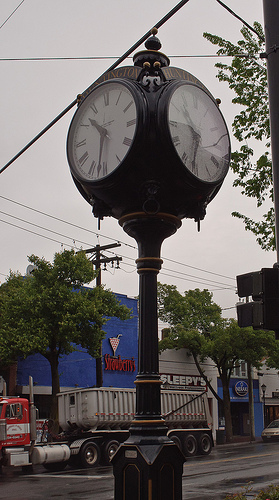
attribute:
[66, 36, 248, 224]
clock — in the picture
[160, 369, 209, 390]
sign — sleepy's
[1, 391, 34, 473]
truck cab — red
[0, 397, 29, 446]
cab — red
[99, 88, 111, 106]
12 — in the picture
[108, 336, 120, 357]
glass — margarita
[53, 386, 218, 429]
trailer — grey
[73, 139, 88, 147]
numeral — in the picture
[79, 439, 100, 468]
wheel — in the picture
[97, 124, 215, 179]
face —   white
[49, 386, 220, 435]
trailer — large